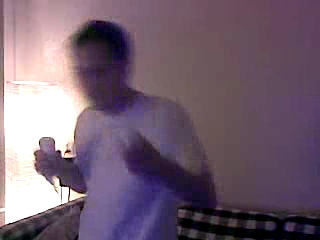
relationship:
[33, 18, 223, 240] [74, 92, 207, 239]
man wearing shirt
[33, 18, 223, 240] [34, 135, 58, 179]
man holds remote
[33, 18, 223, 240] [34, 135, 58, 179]
man holding remote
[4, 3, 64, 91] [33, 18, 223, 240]
window besides man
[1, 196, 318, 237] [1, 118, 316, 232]
sofa in background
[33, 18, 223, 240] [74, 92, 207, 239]
man wears shirt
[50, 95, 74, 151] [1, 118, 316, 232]
lamp i background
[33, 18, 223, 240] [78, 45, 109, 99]
man has face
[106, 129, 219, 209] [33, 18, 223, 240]
arm of man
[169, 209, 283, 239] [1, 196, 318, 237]
pillow from sofa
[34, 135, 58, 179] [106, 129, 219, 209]
remote from arm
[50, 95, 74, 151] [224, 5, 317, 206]
lamp of wall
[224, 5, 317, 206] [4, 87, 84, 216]
wall has light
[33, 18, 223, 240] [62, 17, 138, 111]
man has head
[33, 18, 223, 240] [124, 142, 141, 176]
man has figers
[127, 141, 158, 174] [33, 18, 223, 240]
had of man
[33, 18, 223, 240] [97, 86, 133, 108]
man has eck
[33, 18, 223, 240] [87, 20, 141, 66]
man has hair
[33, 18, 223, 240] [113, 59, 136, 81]
man has ear